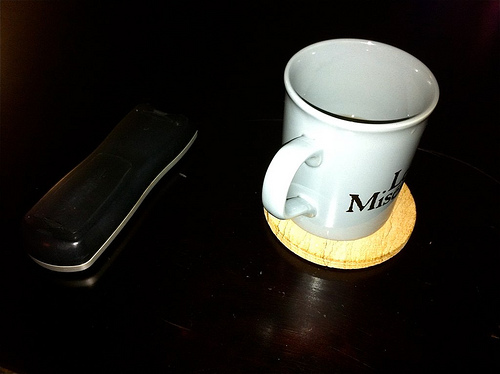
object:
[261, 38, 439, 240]
glass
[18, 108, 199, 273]
phone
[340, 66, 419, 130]
ground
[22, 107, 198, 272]
case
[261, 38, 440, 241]
coffee cup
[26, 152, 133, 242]
battery cap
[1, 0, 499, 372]
coffee table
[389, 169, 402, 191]
lettering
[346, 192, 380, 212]
m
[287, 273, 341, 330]
light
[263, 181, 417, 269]
coast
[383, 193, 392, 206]
black writing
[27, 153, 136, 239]
batter plate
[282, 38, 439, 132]
rim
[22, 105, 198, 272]
remote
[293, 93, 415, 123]
shadow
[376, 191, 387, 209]
black lettering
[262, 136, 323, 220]
handle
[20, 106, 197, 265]
phone bottom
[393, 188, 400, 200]
writing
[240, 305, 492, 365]
wood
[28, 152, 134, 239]
battery compartment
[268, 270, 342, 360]
reflection